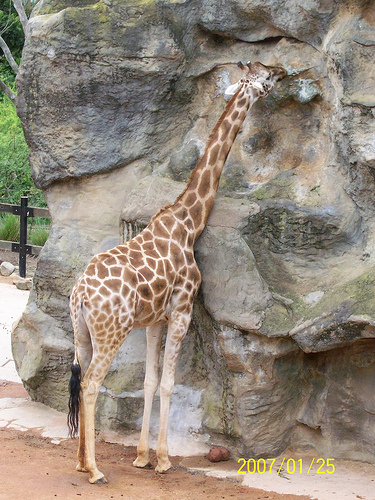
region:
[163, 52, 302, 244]
the giraffe has long neck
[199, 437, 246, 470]
a brown stone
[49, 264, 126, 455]
the giraffe has a long tail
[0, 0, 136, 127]
tree branches beside rock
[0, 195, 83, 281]
a fence beside the rock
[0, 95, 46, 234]
the grass is tall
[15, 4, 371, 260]
the rock is gray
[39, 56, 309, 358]
the giraffe is brown and white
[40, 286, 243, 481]
the giraffe has four legs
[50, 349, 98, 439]
the tail has long black hair on the end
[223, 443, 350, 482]
the date written in yellow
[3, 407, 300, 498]
a patch of wet sand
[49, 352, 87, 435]
a long black tail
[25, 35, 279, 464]
a full grown giraffe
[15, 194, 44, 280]
a black metal post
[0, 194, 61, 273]
a wood and metal fence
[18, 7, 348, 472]
a very large rock formation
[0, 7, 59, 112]
a few tree branches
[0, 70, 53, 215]
a few green plants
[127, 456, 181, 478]
a few pairs of hooves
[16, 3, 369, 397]
a giraffe licking a large rock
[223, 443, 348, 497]
January 25, 2007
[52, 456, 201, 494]
hooves of a giraffe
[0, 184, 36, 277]
a wooden enclosure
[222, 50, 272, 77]
horns of a giraffe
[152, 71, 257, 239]
the mane of a giraffe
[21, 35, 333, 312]
a cliffside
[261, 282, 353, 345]
moss growing on a cliffside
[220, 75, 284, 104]
the ears of a giraffe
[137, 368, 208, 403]
the knees of a giraffe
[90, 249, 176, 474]
brown and tan body of giraffe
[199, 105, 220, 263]
brown and tan neck of giraffe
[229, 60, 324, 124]
brown and tan head of giraffe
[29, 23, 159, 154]
gray and brown rock in enclosure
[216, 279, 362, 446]
gray and brown rock in enclosure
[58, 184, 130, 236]
gray and brown rock in enclosure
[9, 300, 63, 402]
gray and brown rock in enclosure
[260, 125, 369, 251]
gray and brown rock in enclosure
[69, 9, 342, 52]
gray and brown rock in enclosure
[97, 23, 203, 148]
gray and brown rock in enclosure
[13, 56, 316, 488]
Animal has brown spots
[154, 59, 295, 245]
Animal has a long neck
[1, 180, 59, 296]
A fence is in the background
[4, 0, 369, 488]
Photo was taken in the daytime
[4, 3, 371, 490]
Photo was taken outdoors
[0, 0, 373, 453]
A large rock is in the foreground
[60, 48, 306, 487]
Animal in the photo is an african giraffe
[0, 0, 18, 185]
Trees are in the background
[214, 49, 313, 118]
Giraffe's head is near the large stone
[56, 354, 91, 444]
The end of the giraffes tail is black